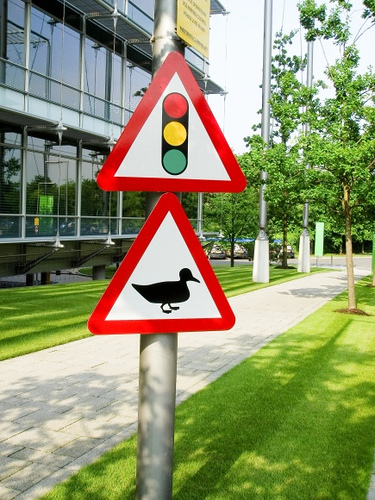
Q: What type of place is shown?
A: It is a lawn.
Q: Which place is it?
A: It is a lawn.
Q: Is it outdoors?
A: Yes, it is outdoors.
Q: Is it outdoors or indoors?
A: It is outdoors.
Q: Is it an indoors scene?
A: No, it is outdoors.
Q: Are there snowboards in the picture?
A: No, there are no snowboards.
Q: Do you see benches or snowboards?
A: No, there are no snowboards or benches.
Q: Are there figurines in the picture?
A: No, there are no figurines.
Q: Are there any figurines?
A: No, there are no figurines.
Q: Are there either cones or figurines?
A: No, there are no figurines or cones.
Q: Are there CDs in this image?
A: No, there are no cds.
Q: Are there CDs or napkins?
A: No, there are no CDs or napkins.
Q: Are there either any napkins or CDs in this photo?
A: No, there are no CDs or napkins.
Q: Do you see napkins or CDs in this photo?
A: No, there are no CDs or napkins.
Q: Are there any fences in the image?
A: No, there are no fences.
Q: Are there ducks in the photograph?
A: Yes, there is a duck.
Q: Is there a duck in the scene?
A: Yes, there is a duck.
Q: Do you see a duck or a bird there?
A: Yes, there is a duck.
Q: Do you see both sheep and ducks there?
A: No, there is a duck but no sheep.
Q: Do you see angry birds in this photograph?
A: No, there are no angry birds.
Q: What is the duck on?
A: The duck is on the sign.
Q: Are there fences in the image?
A: No, there are no fences.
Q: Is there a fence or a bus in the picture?
A: No, there are no fences or buses.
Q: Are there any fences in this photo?
A: No, there are no fences.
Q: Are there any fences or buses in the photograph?
A: No, there are no fences or buses.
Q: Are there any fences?
A: No, there are no fences.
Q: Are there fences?
A: No, there are no fences.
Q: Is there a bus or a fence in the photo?
A: No, there are no fences or buses.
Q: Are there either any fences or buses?
A: No, there are no fences or buses.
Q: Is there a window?
A: Yes, there is a window.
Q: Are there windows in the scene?
A: Yes, there is a window.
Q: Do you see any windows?
A: Yes, there is a window.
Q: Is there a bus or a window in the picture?
A: Yes, there is a window.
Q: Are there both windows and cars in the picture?
A: Yes, there are both a window and a car.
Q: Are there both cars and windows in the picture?
A: Yes, there are both a window and a car.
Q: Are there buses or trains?
A: No, there are no buses or trains.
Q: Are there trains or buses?
A: No, there are no buses or trains.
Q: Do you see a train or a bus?
A: No, there are no buses or trains.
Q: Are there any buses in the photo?
A: No, there are no buses.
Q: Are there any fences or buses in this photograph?
A: No, there are no buses or fences.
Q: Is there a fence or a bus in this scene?
A: No, there are no buses or fences.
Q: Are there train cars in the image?
A: No, there are no train cars.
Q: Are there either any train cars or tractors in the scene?
A: No, there are no train cars or tractors.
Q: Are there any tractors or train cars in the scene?
A: No, there are no train cars or tractors.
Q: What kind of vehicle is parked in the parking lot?
A: The vehicles are cars.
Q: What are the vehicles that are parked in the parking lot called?
A: The vehicles are cars.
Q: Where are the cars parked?
A: The cars are parked in the parking lot.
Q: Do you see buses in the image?
A: No, there are no buses.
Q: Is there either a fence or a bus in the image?
A: No, there are no buses or fences.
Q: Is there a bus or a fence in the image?
A: No, there are no fences or buses.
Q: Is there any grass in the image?
A: Yes, there is grass.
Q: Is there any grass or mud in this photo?
A: Yes, there is grass.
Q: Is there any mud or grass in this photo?
A: Yes, there is grass.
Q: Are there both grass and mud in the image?
A: No, there is grass but no mud.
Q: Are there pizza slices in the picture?
A: No, there are no pizza slices.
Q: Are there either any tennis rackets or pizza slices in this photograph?
A: No, there are no pizza slices or tennis rackets.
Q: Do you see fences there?
A: No, there are no fences.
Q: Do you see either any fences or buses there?
A: No, there are no fences or buses.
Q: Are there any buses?
A: No, there are no buses.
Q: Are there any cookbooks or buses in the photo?
A: No, there are no buses or cookbooks.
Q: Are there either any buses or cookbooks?
A: No, there are no buses or cookbooks.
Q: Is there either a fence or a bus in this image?
A: No, there are no fences or buses.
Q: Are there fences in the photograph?
A: No, there are no fences.